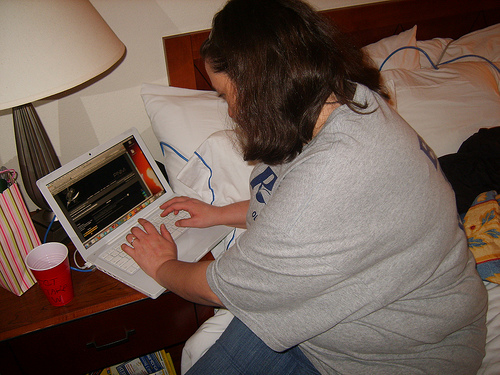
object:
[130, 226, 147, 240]
finger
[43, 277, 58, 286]
words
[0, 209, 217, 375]
nightstand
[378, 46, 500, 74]
cord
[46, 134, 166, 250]
screen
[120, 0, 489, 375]
lady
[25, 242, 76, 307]
cup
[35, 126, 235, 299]
computer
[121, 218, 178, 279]
hand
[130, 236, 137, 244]
ring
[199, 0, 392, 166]
hair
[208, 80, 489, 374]
shirt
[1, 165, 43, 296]
bag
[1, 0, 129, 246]
lamp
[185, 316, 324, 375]
jeans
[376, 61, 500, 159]
pillow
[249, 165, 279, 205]
letter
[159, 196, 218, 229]
hand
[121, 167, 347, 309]
arm